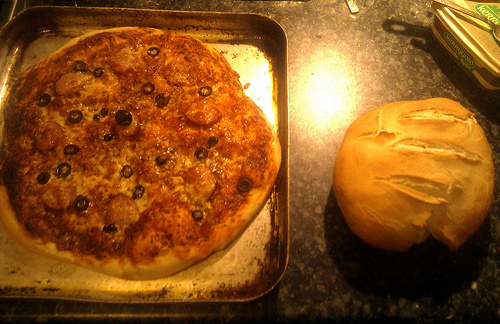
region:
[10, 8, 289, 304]
pizza on a pan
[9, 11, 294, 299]
nice pizza on a pan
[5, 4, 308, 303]
delicious pizza on a pan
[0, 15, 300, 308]
tasty pizza on a pan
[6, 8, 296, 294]
good pizza on a pan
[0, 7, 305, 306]
flavorful pizza on a pan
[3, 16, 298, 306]
round pizza on a pan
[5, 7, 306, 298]
cooked pizza on a pan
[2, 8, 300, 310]
hot pizza on a pan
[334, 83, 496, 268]
nice piece of bread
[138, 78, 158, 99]
a black olive on the pizza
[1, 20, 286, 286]
a pizza on the pan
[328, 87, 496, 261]
a loaf of brown bread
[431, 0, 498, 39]
a gray metal spoon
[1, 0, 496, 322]
a black counter top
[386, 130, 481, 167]
a cut in the bread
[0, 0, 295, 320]
a gray metal pan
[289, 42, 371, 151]
light shining on the table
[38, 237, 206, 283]
a brown pizza crust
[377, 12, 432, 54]
a shadow on the table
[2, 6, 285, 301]
Bread on a tray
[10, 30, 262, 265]
A pizza on the pan.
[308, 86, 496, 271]
A loaf of bread.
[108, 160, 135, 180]
Olive on a pizza.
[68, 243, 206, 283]
The crust of a pizza.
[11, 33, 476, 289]
Pizza next to a loaf of bread.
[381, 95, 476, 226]
Scores on the top of the loaf of bread.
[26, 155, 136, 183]
Three olives on the pizza.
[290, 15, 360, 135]
A light shining on the counter.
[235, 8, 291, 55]
A shadow on the corner of the pizza pan.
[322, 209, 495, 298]
A shadow by the loaf of bread.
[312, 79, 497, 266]
Brown freshly baked bread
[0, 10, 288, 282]
A freshly baked pizza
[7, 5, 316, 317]
A pizza with olives on a pizza pan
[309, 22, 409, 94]
A granite countertop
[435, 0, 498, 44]
A metal spoon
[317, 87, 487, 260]
A crusty loaf of sourdough bread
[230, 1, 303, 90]
The corner of a silver metal baking pan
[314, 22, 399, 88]
A gray kitchen counter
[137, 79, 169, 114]
Olives on a pizza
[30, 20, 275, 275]
A pizza with olives, cheese and tomato sauce